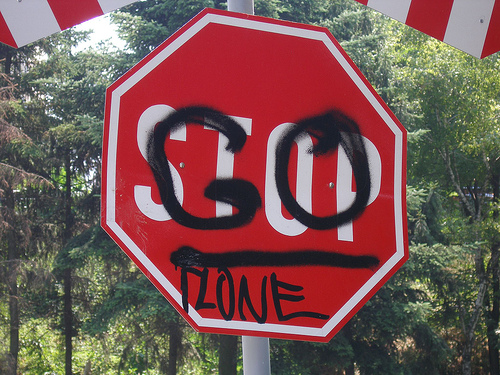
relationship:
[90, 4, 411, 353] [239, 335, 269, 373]
sign on pole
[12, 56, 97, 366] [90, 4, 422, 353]
trees behind sign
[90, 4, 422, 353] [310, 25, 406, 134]
sign has trim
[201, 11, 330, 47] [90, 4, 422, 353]
trim on sign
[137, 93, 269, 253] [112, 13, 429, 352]
letter on sign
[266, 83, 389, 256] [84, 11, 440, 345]
letter on sign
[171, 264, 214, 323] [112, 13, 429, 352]
letter on sign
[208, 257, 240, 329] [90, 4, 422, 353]
letter on sign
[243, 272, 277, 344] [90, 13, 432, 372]
letter on sign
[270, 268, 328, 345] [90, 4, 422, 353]
letter on sign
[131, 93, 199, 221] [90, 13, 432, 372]
letter on sign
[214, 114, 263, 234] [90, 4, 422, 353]
letter on sign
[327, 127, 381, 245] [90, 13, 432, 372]
letter on sign